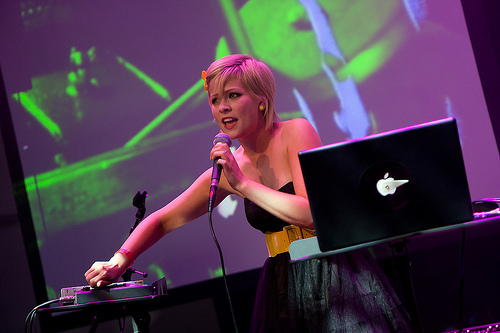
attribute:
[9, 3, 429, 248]
grafitti — green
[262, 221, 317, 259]
belt — yellow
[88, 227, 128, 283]
band — red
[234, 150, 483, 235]
laptop — open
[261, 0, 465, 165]
backgroud — abstract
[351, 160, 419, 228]
logo — white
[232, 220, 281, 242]
belt — yellow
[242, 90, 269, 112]
earring — yellow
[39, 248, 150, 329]
board — grey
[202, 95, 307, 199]
mouth — open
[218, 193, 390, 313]
belt — yellow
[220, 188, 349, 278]
dress — black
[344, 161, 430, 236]
logo — white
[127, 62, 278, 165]
screen — wide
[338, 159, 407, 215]
logo — white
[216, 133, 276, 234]
mic — black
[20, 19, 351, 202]
screen — wide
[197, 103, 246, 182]
mic — black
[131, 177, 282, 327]
cord — black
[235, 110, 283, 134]
earring — yellow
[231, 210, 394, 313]
belt — yellow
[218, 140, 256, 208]
bracelet — yellow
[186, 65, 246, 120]
clip — orange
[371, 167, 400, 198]
logo — apple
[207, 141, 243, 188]
hand — girl's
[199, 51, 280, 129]
hair — blonde, short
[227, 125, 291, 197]
chest — girl's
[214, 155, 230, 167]
finger — white, human, female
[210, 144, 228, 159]
finger — female, white, human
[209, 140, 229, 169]
fingers — human, white, female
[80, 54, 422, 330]
woman — blonde